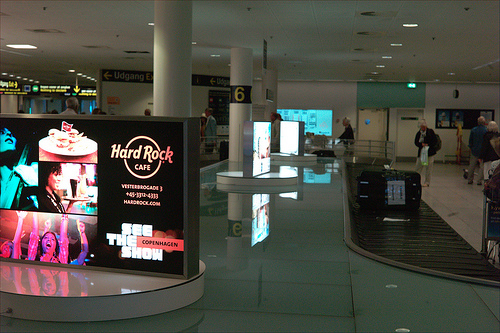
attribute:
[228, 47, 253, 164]
pole — white, support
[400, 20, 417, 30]
light — on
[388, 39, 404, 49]
light — on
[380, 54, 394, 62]
light — on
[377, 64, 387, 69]
light — on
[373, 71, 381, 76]
light — on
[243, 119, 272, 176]
sign — advertisement, illuminated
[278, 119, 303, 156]
sign — advertisement, illuminated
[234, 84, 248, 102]
6 — yellow, sign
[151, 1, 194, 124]
pole — white, support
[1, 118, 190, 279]
sign — electric, illuminated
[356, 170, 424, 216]
luggage — black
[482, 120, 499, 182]
woman — standing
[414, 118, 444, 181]
person — waiting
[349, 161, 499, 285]
conveyor belt — carousel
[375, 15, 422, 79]
lights — recessed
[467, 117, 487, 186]
man — walking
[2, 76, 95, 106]
information signs — lighted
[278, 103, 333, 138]
sign — lit in aqua, location map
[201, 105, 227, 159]
people — standing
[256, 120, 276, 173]
advertising — lighted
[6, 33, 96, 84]
lights — overhead